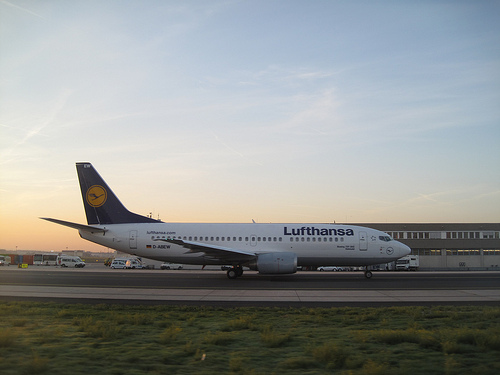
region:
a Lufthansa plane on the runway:
[35, 157, 412, 277]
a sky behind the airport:
[0, 3, 493, 259]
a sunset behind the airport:
[5, 150, 138, 262]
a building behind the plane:
[336, 219, 496, 273]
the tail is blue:
[65, 158, 163, 225]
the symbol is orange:
[82, 181, 106, 208]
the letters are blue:
[280, 225, 353, 237]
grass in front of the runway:
[0, 295, 492, 372]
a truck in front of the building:
[398, 253, 425, 273]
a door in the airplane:
[357, 228, 370, 253]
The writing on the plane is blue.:
[281, 219, 358, 237]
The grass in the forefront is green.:
[200, 320, 358, 367]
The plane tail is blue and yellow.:
[73, 158, 153, 223]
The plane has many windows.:
[150, 229, 347, 244]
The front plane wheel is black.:
[364, 259, 379, 280]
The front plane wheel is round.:
[363, 267, 377, 281]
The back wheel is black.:
[223, 265, 238, 280]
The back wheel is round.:
[224, 266, 238, 281]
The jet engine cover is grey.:
[256, 244, 300, 277]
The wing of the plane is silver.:
[165, 235, 255, 275]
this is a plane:
[25, 121, 498, 341]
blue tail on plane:
[55, 147, 168, 249]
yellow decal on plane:
[68, 165, 118, 207]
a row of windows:
[133, 225, 373, 255]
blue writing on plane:
[280, 220, 370, 240]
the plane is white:
[40, 160, 440, 285]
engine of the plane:
[247, 236, 319, 291]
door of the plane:
[120, 222, 151, 262]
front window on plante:
[372, 228, 397, 249]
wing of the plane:
[143, 191, 252, 285]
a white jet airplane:
[38, 161, 413, 276]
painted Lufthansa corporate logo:
[279, 223, 356, 238]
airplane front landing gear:
[363, 270, 374, 278]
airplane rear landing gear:
[224, 267, 239, 282]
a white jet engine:
[246, 252, 297, 272]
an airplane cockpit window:
[375, 235, 390, 241]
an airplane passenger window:
[338, 235, 343, 242]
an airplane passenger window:
[332, 235, 337, 240]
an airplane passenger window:
[328, 235, 333, 242]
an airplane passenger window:
[321, 234, 327, 242]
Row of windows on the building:
[397, 233, 497, 241]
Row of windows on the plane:
[151, 236, 345, 243]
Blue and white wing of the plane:
[159, 237, 256, 264]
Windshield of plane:
[374, 233, 395, 244]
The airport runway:
[4, 270, 495, 292]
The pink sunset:
[0, 216, 80, 252]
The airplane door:
[357, 230, 369, 252]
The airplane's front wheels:
[362, 270, 372, 280]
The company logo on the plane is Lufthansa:
[280, 223, 355, 236]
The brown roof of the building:
[377, 224, 496, 231]